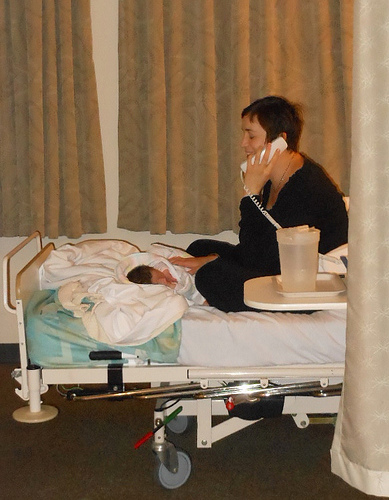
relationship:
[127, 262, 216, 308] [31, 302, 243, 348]
baby on bed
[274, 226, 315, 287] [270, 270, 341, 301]
pitcher on tray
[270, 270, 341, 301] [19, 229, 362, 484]
tray next to bed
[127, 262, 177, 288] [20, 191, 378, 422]
baby on bed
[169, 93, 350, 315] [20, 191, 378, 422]
woman on bed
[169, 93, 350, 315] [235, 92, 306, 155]
woman with hair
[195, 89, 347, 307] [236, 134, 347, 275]
woman on phone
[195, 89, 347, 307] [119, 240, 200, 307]
woman caressing baby